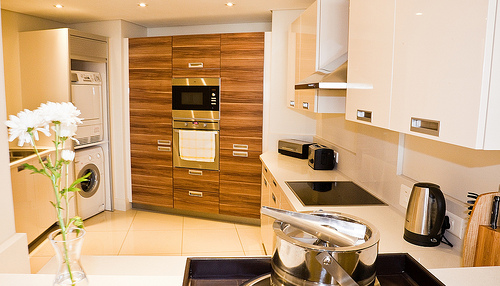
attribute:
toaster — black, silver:
[303, 137, 341, 173]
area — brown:
[170, 35, 221, 50]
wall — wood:
[123, 36, 351, 268]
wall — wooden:
[127, 30, 265, 225]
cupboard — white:
[343, 0, 499, 156]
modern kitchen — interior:
[3, 4, 499, 284]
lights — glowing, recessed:
[52, 1, 239, 16]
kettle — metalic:
[387, 175, 458, 255]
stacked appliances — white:
[66, 38, 126, 224]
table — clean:
[266, 155, 408, 252]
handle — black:
[428, 183, 446, 243]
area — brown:
[223, 174, 258, 190]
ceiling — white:
[25, 4, 287, 35]